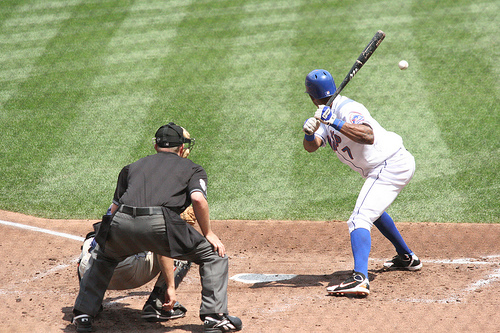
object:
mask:
[155, 121, 196, 159]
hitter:
[302, 69, 423, 299]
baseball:
[398, 60, 410, 70]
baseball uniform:
[315, 94, 417, 277]